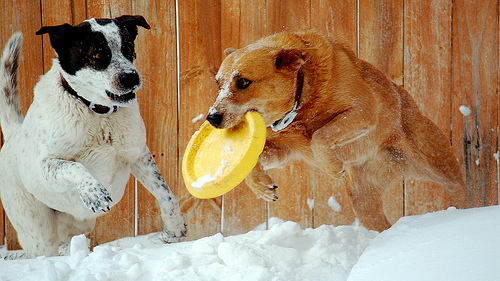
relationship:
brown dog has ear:
[205, 27, 470, 233] [33, 22, 69, 46]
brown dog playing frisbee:
[205, 27, 470, 233] [178, 97, 268, 202]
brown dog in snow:
[205, 27, 470, 233] [4, 202, 495, 276]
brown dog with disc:
[205, 23, 473, 243] [179, 110, 266, 199]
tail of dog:
[0, 30, 25, 141] [0, 15, 189, 281]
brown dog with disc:
[205, 27, 470, 233] [179, 110, 266, 199]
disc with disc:
[183, 110, 267, 198] [179, 110, 266, 199]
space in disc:
[185, 129, 252, 184] [183, 110, 267, 198]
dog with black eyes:
[0, 15, 189, 281] [81, 33, 141, 63]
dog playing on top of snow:
[0, 15, 189, 281] [4, 202, 495, 276]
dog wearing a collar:
[181, 32, 459, 210] [271, 45, 320, 145]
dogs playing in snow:
[0, 4, 475, 262] [6, 228, 460, 281]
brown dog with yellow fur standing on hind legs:
[205, 27, 470, 233] [85, 128, 195, 264]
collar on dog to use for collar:
[251, 100, 322, 141] [271, 66, 306, 131]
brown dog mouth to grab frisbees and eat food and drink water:
[205, 27, 470, 233] [185, 153, 265, 281]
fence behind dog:
[0, 0, 500, 252] [328, 98, 405, 174]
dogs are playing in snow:
[0, 14, 466, 258] [1, 187, 496, 279]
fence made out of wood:
[3, 1, 498, 212] [323, 108, 497, 174]